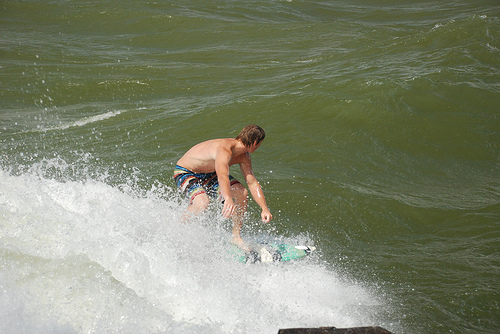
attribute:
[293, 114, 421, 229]
water — green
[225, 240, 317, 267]
surfboard — green black & white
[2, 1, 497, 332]
ocean waves — white, green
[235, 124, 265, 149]
hair — brown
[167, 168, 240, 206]
shorts — blue, yellow, red, black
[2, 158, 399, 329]
waves — green, white, crashing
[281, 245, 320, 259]
surfboard — green, white, black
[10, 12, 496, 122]
waves — white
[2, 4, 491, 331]
water — green, dark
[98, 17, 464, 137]
ocean — green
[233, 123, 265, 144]
hair — brown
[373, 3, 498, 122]
waves — crashing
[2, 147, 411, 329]
wave — green, white, green and white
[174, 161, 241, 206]
shorts — colorful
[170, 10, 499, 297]
waves — green and white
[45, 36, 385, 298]
waves — green, white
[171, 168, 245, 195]
swimming trunks — colorful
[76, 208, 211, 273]
waves — white, green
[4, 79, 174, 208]
waves — white, green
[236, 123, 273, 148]
hair — brown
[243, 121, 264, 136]
hair — brown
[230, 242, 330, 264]
surfboard — white, black and green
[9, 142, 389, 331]
waves — green, white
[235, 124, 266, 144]
hair — short